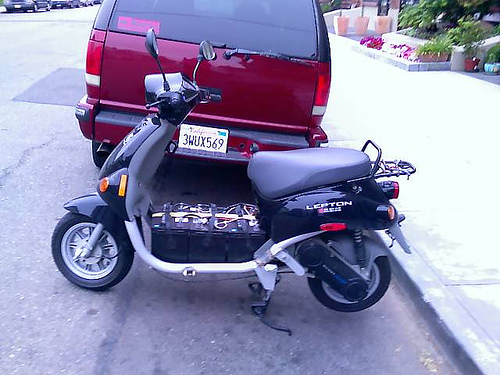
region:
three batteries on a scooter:
[148, 199, 271, 261]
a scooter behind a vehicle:
[49, 25, 418, 321]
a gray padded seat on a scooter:
[246, 146, 371, 192]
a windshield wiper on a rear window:
[222, 40, 316, 68]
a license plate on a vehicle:
[176, 119, 231, 155]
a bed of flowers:
[361, 35, 421, 56]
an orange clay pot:
[332, 12, 349, 36]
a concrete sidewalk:
[321, 37, 498, 374]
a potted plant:
[454, 20, 482, 74]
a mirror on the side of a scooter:
[189, 37, 222, 90]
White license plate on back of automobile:
[176, 122, 230, 157]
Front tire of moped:
[48, 198, 135, 293]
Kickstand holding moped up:
[245, 269, 297, 340]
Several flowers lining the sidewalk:
[357, 33, 421, 75]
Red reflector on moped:
[320, 223, 348, 230]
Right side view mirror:
[191, 38, 217, 85]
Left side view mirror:
[141, 28, 170, 92]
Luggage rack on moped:
[361, 138, 418, 180]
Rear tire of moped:
[305, 235, 395, 314]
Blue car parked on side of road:
[1, 0, 52, 11]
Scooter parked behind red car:
[48, 27, 418, 312]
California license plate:
[174, 122, 232, 157]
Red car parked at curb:
[73, 0, 335, 168]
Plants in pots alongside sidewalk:
[411, 3, 492, 68]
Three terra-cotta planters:
[333, 12, 398, 36]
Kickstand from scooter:
[246, 302, 313, 336]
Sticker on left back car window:
[111, 15, 164, 38]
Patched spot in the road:
[17, 62, 83, 124]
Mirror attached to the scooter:
[142, 28, 171, 88]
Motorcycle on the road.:
[36, 17, 465, 339]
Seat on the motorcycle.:
[240, 127, 482, 260]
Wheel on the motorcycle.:
[2, 178, 164, 323]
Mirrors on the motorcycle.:
[130, 16, 233, 103]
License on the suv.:
[170, 74, 260, 205]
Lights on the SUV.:
[71, 7, 142, 109]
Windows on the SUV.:
[95, 4, 379, 88]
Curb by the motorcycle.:
[384, 229, 491, 359]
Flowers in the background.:
[335, 12, 482, 70]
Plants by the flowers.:
[403, 13, 494, 57]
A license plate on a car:
[178, 123, 228, 153]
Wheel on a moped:
[50, 204, 130, 287]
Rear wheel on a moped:
[307, 229, 389, 310]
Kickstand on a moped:
[247, 256, 297, 336]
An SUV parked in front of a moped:
[80, 0, 332, 161]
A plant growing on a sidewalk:
[417, 38, 450, 59]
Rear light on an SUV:
[313, 73, 327, 115]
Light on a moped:
[98, 174, 110, 191]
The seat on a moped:
[248, 146, 371, 193]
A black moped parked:
[50, 28, 411, 311]